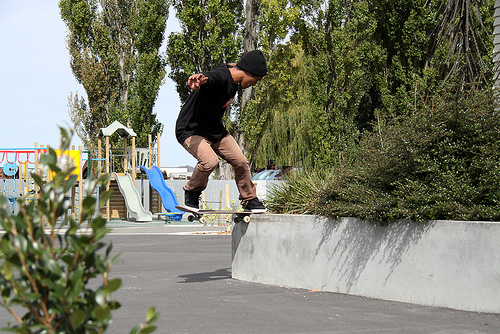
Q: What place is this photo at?
A: It is at the park.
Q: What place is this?
A: It is a park.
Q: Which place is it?
A: It is a park.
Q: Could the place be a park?
A: Yes, it is a park.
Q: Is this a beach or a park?
A: It is a park.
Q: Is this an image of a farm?
A: No, the picture is showing a park.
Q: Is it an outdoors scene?
A: Yes, it is outdoors.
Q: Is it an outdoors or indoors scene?
A: It is outdoors.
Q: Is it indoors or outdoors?
A: It is outdoors.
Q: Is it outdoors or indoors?
A: It is outdoors.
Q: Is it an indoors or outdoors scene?
A: It is outdoors.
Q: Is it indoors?
A: No, it is outdoors.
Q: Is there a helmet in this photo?
A: No, there are no helmets.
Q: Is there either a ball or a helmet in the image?
A: No, there are no helmets or balls.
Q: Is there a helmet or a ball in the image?
A: No, there are no helmets or balls.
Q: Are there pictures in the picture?
A: No, there are no pictures.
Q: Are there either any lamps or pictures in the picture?
A: No, there are no pictures or lamps.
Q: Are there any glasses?
A: No, there are no glasses.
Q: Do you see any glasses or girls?
A: No, there are no glasses or girls.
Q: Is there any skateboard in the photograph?
A: Yes, there is a skateboard.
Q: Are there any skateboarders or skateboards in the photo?
A: Yes, there is a skateboard.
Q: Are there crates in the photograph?
A: No, there are no crates.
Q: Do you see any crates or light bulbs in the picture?
A: No, there are no crates or light bulbs.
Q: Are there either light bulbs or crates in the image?
A: No, there are no crates or light bulbs.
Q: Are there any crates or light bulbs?
A: No, there are no crates or light bulbs.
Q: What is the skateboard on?
A: The skateboard is on the wall.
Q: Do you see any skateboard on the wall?
A: Yes, there is a skateboard on the wall.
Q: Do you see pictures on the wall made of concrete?
A: No, there is a skateboard on the wall.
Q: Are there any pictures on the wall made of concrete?
A: No, there is a skateboard on the wall.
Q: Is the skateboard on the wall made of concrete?
A: Yes, the skateboard is on the wall.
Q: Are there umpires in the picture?
A: No, there are no umpires.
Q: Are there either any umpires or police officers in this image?
A: No, there are no umpires or police officers.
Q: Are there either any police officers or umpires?
A: No, there are no umpires or police officers.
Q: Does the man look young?
A: Yes, the man is young.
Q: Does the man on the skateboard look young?
A: Yes, the man is young.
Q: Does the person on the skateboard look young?
A: Yes, the man is young.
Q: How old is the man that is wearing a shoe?
A: The man is young.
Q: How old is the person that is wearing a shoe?
A: The man is young.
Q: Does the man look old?
A: No, the man is young.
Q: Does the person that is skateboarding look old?
A: No, the man is young.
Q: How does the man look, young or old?
A: The man is young.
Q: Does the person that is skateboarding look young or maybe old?
A: The man is young.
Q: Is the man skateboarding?
A: Yes, the man is skateboarding.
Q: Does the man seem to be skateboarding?
A: Yes, the man is skateboarding.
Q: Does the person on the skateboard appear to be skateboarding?
A: Yes, the man is skateboarding.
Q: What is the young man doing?
A: The man is skateboarding.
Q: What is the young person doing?
A: The man is skateboarding.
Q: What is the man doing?
A: The man is skateboarding.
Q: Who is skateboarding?
A: The man is skateboarding.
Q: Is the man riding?
A: No, the man is skateboarding.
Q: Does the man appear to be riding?
A: No, the man is skateboarding.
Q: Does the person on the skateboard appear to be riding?
A: No, the man is skateboarding.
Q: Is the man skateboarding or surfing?
A: The man is skateboarding.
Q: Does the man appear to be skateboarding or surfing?
A: The man is skateboarding.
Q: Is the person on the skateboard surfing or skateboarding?
A: The man is skateboarding.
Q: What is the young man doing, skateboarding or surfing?
A: The man is skateboarding.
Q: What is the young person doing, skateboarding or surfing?
A: The man is skateboarding.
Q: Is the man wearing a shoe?
A: Yes, the man is wearing a shoe.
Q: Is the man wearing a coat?
A: No, the man is wearing a shoe.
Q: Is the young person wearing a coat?
A: No, the man is wearing a shoe.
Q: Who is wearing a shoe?
A: The man is wearing a shoe.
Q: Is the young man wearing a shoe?
A: Yes, the man is wearing a shoe.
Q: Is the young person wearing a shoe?
A: Yes, the man is wearing a shoe.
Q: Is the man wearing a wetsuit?
A: No, the man is wearing a shoe.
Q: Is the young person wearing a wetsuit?
A: No, the man is wearing a shoe.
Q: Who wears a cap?
A: The man wears a cap.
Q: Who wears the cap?
A: The man wears a cap.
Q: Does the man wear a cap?
A: Yes, the man wears a cap.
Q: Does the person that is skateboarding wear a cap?
A: Yes, the man wears a cap.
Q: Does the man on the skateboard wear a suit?
A: No, the man wears a cap.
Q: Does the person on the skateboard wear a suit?
A: No, the man wears a cap.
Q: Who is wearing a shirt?
A: The man is wearing a shirt.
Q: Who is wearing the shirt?
A: The man is wearing a shirt.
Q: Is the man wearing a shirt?
A: Yes, the man is wearing a shirt.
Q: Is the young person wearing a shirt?
A: Yes, the man is wearing a shirt.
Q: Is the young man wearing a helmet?
A: No, the man is wearing a shirt.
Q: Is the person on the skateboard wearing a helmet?
A: No, the man is wearing a shirt.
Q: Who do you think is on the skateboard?
A: The man is on the skateboard.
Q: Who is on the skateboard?
A: The man is on the skateboard.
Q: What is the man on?
A: The man is on the skateboard.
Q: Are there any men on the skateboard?
A: Yes, there is a man on the skateboard.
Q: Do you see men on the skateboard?
A: Yes, there is a man on the skateboard.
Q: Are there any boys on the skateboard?
A: No, there is a man on the skateboard.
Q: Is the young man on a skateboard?
A: Yes, the man is on a skateboard.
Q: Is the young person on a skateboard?
A: Yes, the man is on a skateboard.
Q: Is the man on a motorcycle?
A: No, the man is on a skateboard.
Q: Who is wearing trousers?
A: The man is wearing trousers.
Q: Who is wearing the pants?
A: The man is wearing trousers.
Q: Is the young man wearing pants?
A: Yes, the man is wearing pants.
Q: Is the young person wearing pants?
A: Yes, the man is wearing pants.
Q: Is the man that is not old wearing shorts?
A: No, the man is wearing pants.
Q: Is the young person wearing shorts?
A: No, the man is wearing pants.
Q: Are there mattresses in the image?
A: No, there are no mattresses.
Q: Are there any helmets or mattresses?
A: No, there are no mattresses or helmets.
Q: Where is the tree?
A: The tree is in the park.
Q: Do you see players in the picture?
A: No, there are no players.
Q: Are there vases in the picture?
A: No, there are no vases.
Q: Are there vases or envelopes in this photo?
A: No, there are no vases or envelopes.